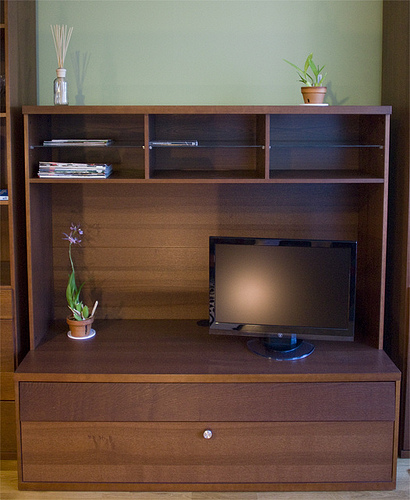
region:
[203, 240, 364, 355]
monitor has black frame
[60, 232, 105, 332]
purple flower in pot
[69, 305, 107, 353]
pot is light brown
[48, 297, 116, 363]
pot on brown table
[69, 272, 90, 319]
green leaves on plant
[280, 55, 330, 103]
pot on top of console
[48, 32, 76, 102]
small jar on top of console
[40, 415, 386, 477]
brown drawer below monitor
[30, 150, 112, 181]
magazines are above plant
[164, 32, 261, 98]
green wall behind console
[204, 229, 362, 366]
tv frame is black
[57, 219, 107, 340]
plant on the tv stand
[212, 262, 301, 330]
light shining on tv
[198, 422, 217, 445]
silver knob on drawer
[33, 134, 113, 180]
magazines on the tv stand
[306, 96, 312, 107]
black spot on pot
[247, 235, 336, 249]
reflection on tv frame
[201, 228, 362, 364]
the tv is off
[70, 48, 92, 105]
shadow of sticks on wall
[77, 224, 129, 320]
shadow of flower on tv stand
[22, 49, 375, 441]
this is an entertainment center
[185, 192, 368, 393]
the tv is black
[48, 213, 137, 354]
the flower is purple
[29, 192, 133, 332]
the flower is in a pot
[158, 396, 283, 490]
the dresser is wood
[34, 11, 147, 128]
this is an air freshener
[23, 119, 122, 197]
a pile of magazines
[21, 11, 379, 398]
there are two plants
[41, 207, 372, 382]
first shelf has a plant and tv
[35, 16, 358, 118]
top shelf is plant and air freshener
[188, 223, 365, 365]
Television on the cabinet.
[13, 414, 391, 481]
Drawer in the cabinet.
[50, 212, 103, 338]
Potted plant on the cabinet.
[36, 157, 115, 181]
Magazines on the shelf.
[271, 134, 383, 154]
Glass shelf on the cabinet.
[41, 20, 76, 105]
Sticks in the bottle.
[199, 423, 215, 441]
Knob on the drawer.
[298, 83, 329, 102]
Terra cotta color on the pot.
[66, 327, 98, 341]
Plate under the planter.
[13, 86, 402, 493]
Wooden cabinet in the forefront.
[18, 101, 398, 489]
Brown wooden desk shelf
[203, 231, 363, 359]
Computer monitor on shelf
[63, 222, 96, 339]
Tall flower in a pot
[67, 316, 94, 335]
Small terracotta pot on a shelf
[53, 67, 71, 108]
Glass jar on top of shelf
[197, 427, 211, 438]
Metal knob on front of shelf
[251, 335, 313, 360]
Round base of computer monitor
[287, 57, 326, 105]
Green plant in a pot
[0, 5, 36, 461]
Tall wooden shelf on floor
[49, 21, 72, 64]
Wooden sticks in glass jar